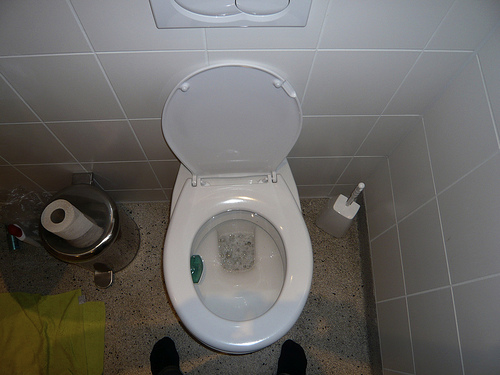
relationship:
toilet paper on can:
[40, 200, 92, 240] [38, 172, 142, 288]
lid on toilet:
[159, 61, 302, 178] [135, 58, 340, 370]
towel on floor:
[11, 307, 101, 367] [0, 287, 105, 294]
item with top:
[9, 224, 41, 249] [6, 222, 21, 238]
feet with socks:
[144, 330, 310, 371] [142, 328, 310, 373]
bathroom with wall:
[4, 12, 497, 365] [357, 24, 498, 374]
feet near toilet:
[128, 308, 330, 370] [117, 65, 379, 370]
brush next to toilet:
[317, 165, 371, 232] [158, 59, 315, 356]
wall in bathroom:
[355, 17, 498, 373] [4, 12, 497, 365]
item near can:
[9, 215, 34, 249] [38, 172, 142, 288]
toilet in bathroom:
[114, 84, 326, 369] [4, 12, 497, 365]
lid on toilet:
[117, 46, 299, 205] [158, 59, 315, 356]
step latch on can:
[91, 269, 118, 294] [28, 177, 143, 292]